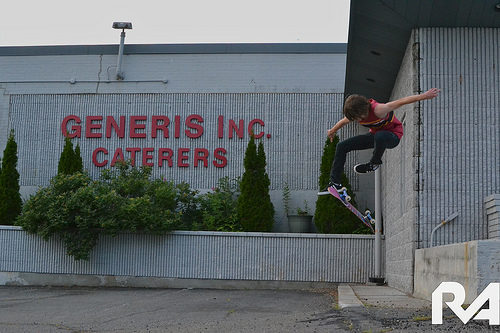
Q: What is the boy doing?
A: Jumping while skateboarding.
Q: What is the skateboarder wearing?
A: Red shirt and blue jeans.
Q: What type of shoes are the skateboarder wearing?
A: Dark colored tennis shoes.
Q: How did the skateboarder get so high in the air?
A: The skateboarder flew off the dock.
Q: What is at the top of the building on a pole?
A: A security light.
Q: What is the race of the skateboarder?
A: Caucasian.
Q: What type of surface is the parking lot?
A: Asphalt.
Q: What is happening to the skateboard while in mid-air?
A: The skateboard is being flipped upside down.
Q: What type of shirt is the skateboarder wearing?
A: A sleeveless shirt.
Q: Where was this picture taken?
A: Parking lot.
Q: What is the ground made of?
A: Concrete.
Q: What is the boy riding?
A: A skateboard.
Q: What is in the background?
A: A building.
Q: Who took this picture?
A: A friend.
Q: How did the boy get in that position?
A: Jump.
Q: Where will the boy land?
A: On the skateboard.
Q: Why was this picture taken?
A: Memories.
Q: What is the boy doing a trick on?
A: A skateboard.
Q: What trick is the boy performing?
A: An ollie.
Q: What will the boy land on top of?
A: Pavement.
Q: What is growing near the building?
A: Bushes.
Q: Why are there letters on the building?
A: To display the building's name.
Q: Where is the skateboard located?
A: In mid air.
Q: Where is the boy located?
A: In mid air.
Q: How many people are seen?
A: 1.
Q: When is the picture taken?
A: Daytime.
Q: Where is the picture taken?
A: Outside a building.